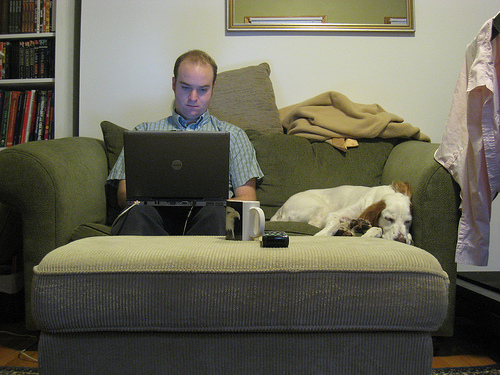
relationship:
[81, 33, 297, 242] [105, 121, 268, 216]
man on laptop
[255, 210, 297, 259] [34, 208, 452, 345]
remote on footstool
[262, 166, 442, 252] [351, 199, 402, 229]
dog has ears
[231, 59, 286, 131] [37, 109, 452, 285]
pillow on couch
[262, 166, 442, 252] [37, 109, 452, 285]
do laying couch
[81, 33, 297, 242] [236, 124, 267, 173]
man has shirt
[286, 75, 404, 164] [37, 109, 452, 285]
blanket on couch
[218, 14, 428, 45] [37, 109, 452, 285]
mirror above couch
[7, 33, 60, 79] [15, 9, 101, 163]
books on shelves